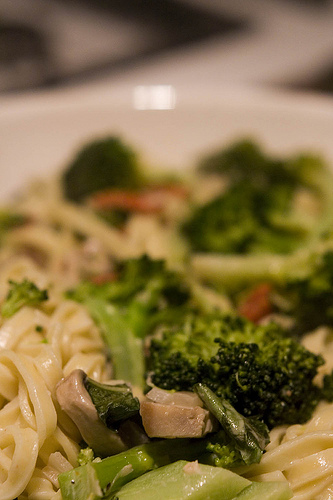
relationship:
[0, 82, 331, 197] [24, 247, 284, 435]
plate full of some food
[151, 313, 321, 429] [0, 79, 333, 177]
broccoli on plate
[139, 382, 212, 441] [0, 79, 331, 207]
brown on plate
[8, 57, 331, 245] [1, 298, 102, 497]
plate of noodles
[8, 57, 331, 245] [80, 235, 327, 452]
plate of broccoli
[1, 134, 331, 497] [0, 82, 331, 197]
food on plate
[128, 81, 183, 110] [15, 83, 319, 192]
light shining down on plate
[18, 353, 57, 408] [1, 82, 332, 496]
noodles on plate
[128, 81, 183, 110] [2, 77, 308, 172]
light reflecting on plate